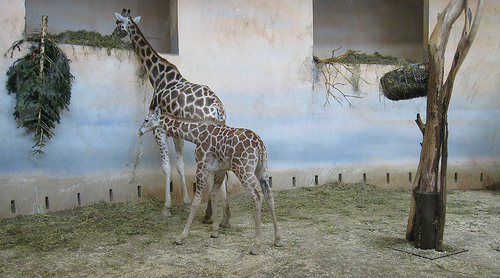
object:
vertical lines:
[7, 171, 483, 213]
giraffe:
[137, 104, 287, 256]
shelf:
[22, 35, 178, 56]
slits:
[44, 196, 51, 211]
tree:
[402, 0, 487, 252]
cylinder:
[406, 186, 448, 251]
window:
[312, 0, 430, 66]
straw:
[330, 50, 428, 65]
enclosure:
[0, 1, 499, 277]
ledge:
[313, 61, 424, 67]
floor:
[0, 190, 500, 278]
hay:
[0, 180, 500, 252]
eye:
[142, 117, 150, 123]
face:
[137, 115, 156, 133]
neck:
[126, 17, 178, 85]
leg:
[153, 128, 172, 210]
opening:
[24, 1, 177, 55]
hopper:
[24, 0, 178, 54]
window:
[23, 0, 178, 55]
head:
[111, 7, 142, 40]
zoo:
[0, 0, 499, 278]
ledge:
[26, 39, 181, 58]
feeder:
[378, 68, 428, 102]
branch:
[38, 13, 49, 155]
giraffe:
[110, 7, 233, 228]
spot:
[242, 138, 254, 149]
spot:
[246, 155, 258, 161]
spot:
[233, 157, 243, 166]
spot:
[248, 181, 260, 190]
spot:
[168, 117, 178, 125]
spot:
[188, 121, 196, 133]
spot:
[194, 98, 204, 108]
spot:
[176, 95, 186, 108]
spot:
[130, 33, 141, 44]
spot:
[144, 45, 154, 56]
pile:
[403, 0, 467, 248]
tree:
[6, 15, 74, 157]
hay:
[28, 28, 137, 56]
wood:
[425, 144, 439, 173]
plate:
[385, 237, 473, 261]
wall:
[0, 0, 500, 219]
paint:
[268, 116, 347, 130]